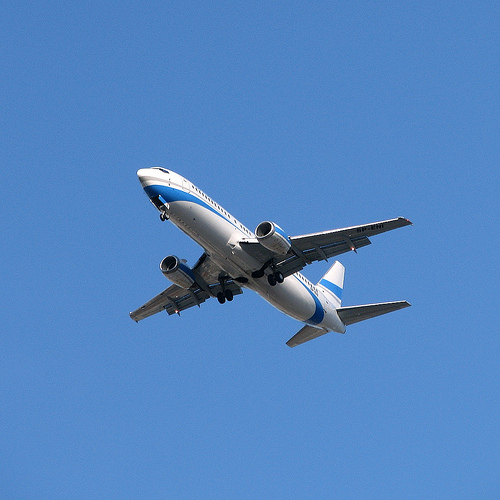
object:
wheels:
[216, 270, 284, 304]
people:
[125, 160, 422, 353]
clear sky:
[0, 0, 498, 495]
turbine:
[253, 220, 292, 256]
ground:
[408, 128, 468, 186]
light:
[346, 236, 356, 254]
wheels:
[159, 212, 170, 221]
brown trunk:
[343, 22, 477, 124]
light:
[172, 307, 182, 314]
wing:
[240, 215, 413, 282]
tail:
[315, 259, 350, 311]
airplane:
[129, 166, 412, 350]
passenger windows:
[195, 183, 253, 235]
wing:
[336, 297, 411, 329]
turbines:
[159, 254, 195, 289]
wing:
[129, 255, 242, 322]